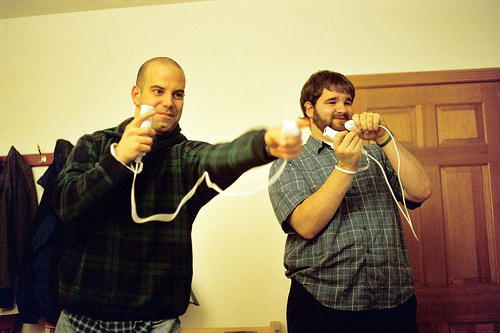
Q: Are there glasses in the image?
A: No, there are no glasses.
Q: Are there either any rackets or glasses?
A: No, there are no glasses or rackets.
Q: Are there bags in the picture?
A: No, there are no bags.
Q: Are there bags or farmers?
A: No, there are no bags or farmers.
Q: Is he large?
A: Yes, the guy is large.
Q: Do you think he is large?
A: Yes, the guy is large.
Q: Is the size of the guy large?
A: Yes, the guy is large.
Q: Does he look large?
A: Yes, the guy is large.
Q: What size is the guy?
A: The guy is large.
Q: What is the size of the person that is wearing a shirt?
A: The guy is large.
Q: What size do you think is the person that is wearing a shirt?
A: The guy is large.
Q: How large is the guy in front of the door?
A: The guy is large.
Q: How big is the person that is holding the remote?
A: The guy is large.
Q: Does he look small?
A: No, the guy is large.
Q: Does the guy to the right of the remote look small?
A: No, the guy is large.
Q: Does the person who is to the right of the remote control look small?
A: No, the guy is large.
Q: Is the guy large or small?
A: The guy is large.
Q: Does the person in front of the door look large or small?
A: The guy is large.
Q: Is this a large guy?
A: Yes, this is a large guy.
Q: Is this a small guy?
A: No, this is a large guy.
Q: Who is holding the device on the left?
A: The guy is holding the remote control.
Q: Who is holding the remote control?
A: The guy is holding the remote control.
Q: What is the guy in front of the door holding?
A: The guy is holding the remote.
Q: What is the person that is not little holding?
A: The guy is holding the remote.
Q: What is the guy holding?
A: The guy is holding the remote.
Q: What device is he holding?
A: The guy is holding the remote.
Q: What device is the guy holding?
A: The guy is holding the remote.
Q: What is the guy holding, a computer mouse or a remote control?
A: The guy is holding a remote control.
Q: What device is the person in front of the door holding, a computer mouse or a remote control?
A: The guy is holding a remote control.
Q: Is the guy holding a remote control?
A: Yes, the guy is holding a remote control.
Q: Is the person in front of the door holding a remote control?
A: Yes, the guy is holding a remote control.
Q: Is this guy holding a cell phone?
A: No, the guy is holding a remote control.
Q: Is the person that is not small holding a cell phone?
A: No, the guy is holding a remote control.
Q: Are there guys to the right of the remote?
A: Yes, there is a guy to the right of the remote.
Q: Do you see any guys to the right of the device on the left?
A: Yes, there is a guy to the right of the remote.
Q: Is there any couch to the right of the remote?
A: No, there is a guy to the right of the remote.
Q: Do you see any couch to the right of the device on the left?
A: No, there is a guy to the right of the remote.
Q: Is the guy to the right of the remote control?
A: Yes, the guy is to the right of the remote control.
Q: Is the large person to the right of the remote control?
A: Yes, the guy is to the right of the remote control.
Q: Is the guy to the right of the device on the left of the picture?
A: Yes, the guy is to the right of the remote control.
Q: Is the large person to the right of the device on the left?
A: Yes, the guy is to the right of the remote control.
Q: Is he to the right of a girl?
A: No, the guy is to the right of the remote control.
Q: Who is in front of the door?
A: The guy is in front of the door.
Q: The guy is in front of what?
A: The guy is in front of the door.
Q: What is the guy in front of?
A: The guy is in front of the door.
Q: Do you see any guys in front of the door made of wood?
A: Yes, there is a guy in front of the door.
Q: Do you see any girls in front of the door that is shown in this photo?
A: No, there is a guy in front of the door.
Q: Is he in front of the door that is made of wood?
A: Yes, the guy is in front of the door.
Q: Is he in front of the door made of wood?
A: Yes, the guy is in front of the door.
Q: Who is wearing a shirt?
A: The guy is wearing a shirt.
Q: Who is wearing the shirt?
A: The guy is wearing a shirt.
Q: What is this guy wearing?
A: The guy is wearing a shirt.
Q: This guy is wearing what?
A: The guy is wearing a shirt.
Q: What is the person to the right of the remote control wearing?
A: The guy is wearing a shirt.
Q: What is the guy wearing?
A: The guy is wearing a shirt.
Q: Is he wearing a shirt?
A: Yes, the guy is wearing a shirt.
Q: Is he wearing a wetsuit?
A: No, the guy is wearing a shirt.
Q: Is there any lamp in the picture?
A: No, there are no lamps.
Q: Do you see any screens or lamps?
A: No, there are no lamps or screens.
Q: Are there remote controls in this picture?
A: Yes, there is a remote control.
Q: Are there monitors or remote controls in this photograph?
A: Yes, there is a remote control.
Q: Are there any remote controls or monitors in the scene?
A: Yes, there is a remote control.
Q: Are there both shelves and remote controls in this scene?
A: No, there is a remote control but no shelves.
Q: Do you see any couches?
A: No, there are no couches.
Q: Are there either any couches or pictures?
A: No, there are no couches or pictures.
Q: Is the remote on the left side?
A: Yes, the remote is on the left of the image.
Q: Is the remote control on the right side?
A: No, the remote control is on the left of the image.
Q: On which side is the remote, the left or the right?
A: The remote is on the left of the image.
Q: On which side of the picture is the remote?
A: The remote is on the left of the image.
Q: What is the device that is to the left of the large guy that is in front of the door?
A: The device is a remote control.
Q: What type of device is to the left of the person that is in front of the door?
A: The device is a remote control.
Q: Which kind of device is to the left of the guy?
A: The device is a remote control.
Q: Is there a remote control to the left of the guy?
A: Yes, there is a remote control to the left of the guy.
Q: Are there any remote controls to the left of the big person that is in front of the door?
A: Yes, there is a remote control to the left of the guy.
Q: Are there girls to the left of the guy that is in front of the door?
A: No, there is a remote control to the left of the guy.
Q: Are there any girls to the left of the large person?
A: No, there is a remote control to the left of the guy.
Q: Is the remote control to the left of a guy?
A: Yes, the remote control is to the left of a guy.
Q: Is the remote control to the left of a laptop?
A: No, the remote control is to the left of a guy.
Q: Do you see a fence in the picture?
A: No, there are no fences.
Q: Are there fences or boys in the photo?
A: No, there are no fences or boys.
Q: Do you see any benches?
A: No, there are no benches.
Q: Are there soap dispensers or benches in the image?
A: No, there are no benches or soap dispensers.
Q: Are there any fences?
A: No, there are no fences.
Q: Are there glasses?
A: No, there are no glasses.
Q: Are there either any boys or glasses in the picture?
A: No, there are no glasses or boys.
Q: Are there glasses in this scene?
A: No, there are no glasses.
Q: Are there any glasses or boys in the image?
A: No, there are no glasses or boys.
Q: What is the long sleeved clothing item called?
A: The clothing item is a shirt.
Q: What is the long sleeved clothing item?
A: The clothing item is a shirt.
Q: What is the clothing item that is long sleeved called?
A: The clothing item is a shirt.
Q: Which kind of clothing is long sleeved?
A: The clothing is a shirt.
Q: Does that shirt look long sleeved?
A: Yes, the shirt is long sleeved.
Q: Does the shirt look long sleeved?
A: Yes, the shirt is long sleeved.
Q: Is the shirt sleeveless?
A: No, the shirt is long sleeved.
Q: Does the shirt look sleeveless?
A: No, the shirt is long sleeved.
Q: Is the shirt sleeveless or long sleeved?
A: The shirt is long sleeved.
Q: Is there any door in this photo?
A: Yes, there is a door.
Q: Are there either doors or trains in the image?
A: Yes, there is a door.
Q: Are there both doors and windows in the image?
A: No, there is a door but no windows.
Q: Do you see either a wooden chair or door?
A: Yes, there is a wood door.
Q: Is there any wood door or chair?
A: Yes, there is a wood door.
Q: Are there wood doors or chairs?
A: Yes, there is a wood door.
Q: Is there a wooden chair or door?
A: Yes, there is a wood door.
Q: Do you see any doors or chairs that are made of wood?
A: Yes, the door is made of wood.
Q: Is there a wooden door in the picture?
A: Yes, there is a wood door.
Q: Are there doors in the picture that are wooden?
A: Yes, there is a door that is wooden.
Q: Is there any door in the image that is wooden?
A: Yes, there is a door that is wooden.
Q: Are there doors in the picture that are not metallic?
A: Yes, there is a wooden door.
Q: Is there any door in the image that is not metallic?
A: Yes, there is a wooden door.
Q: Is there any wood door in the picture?
A: Yes, there is a door that is made of wood.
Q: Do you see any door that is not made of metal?
A: Yes, there is a door that is made of wood.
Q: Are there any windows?
A: No, there are no windows.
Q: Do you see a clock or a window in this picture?
A: No, there are no windows or clocks.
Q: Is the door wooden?
A: Yes, the door is wooden.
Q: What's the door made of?
A: The door is made of wood.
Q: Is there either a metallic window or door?
A: No, there is a door but it is wooden.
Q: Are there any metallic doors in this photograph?
A: No, there is a door but it is wooden.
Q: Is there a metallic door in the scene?
A: No, there is a door but it is wooden.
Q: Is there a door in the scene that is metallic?
A: No, there is a door but it is wooden.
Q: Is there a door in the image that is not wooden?
A: No, there is a door but it is wooden.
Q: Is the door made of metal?
A: No, the door is made of wood.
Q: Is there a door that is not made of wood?
A: No, there is a door but it is made of wood.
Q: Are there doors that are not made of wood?
A: No, there is a door but it is made of wood.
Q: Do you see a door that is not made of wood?
A: No, there is a door but it is made of wood.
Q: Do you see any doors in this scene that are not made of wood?
A: No, there is a door but it is made of wood.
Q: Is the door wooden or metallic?
A: The door is wooden.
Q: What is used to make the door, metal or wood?
A: The door is made of wood.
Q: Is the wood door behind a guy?
A: Yes, the door is behind a guy.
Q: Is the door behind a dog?
A: No, the door is behind a guy.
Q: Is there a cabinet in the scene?
A: No, there are no cabinets.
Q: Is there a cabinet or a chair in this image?
A: No, there are no cabinets or chairs.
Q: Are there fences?
A: No, there are no fences.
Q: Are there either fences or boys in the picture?
A: No, there are no fences or boys.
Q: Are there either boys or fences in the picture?
A: No, there are no fences or boys.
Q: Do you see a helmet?
A: No, there are no helmets.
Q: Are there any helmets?
A: No, there are no helmets.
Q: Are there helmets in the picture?
A: No, there are no helmets.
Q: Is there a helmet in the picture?
A: No, there are no helmets.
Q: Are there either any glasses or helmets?
A: No, there are no helmets or glasses.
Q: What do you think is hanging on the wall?
A: The jacket is hanging on the wall.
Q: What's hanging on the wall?
A: The jacket is hanging on the wall.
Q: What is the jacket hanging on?
A: The jacket is hanging on the wall.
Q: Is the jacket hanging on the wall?
A: Yes, the jacket is hanging on the wall.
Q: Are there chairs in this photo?
A: No, there are no chairs.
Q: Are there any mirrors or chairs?
A: No, there are no chairs or mirrors.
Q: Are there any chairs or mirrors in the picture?
A: No, there are no chairs or mirrors.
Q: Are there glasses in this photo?
A: No, there are no glasses.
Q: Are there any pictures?
A: No, there are no pictures.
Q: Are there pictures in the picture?
A: No, there are no pictures.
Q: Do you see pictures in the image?
A: No, there are no pictures.